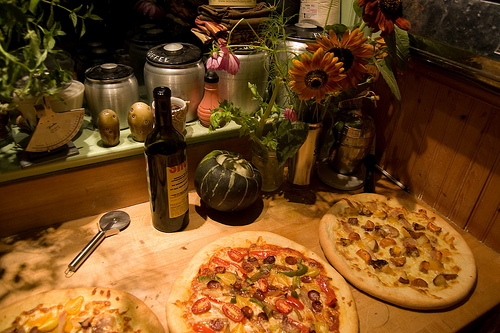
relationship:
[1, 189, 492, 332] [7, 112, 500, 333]
pizza on wooden surface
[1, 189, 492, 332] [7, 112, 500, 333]
pizza on counter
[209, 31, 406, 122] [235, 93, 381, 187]
flower in vase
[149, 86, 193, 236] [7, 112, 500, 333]
bottle on counter